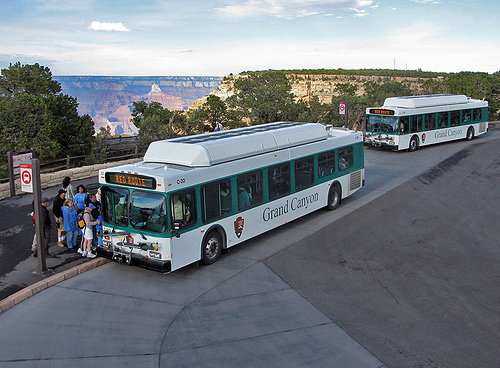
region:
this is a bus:
[94, 120, 368, 273]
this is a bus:
[364, 85, 496, 149]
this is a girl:
[78, 200, 99, 259]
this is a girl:
[59, 193, 86, 248]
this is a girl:
[37, 191, 58, 263]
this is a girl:
[49, 183, 71, 248]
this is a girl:
[54, 165, 80, 240]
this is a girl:
[65, 182, 100, 234]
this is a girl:
[84, 189, 103, 251]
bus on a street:
[95, 138, 400, 269]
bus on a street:
[360, 83, 492, 159]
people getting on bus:
[56, 175, 97, 260]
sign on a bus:
[102, 170, 162, 192]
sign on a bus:
[368, 102, 394, 120]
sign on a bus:
[251, 188, 332, 228]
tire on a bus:
[201, 225, 236, 265]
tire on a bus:
[322, 180, 359, 208]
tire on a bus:
[405, 135, 430, 151]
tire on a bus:
[458, 126, 478, 143]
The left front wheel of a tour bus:
[194, 222, 230, 266]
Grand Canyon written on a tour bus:
[253, 187, 326, 227]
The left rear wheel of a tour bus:
[317, 174, 346, 214]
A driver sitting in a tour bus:
[156, 189, 195, 231]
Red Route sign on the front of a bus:
[102, 170, 153, 193]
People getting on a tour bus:
[52, 174, 104, 262]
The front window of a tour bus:
[92, 180, 170, 240]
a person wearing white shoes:
[77, 245, 99, 262]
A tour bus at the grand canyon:
[89, 113, 371, 278]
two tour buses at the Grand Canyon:
[94, 87, 492, 283]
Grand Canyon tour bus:
[82, 117, 372, 282]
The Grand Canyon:
[46, 73, 253, 138]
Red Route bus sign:
[103, 170, 160, 190]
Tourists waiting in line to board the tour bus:
[30, 168, 133, 275]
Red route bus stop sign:
[16, 155, 51, 280]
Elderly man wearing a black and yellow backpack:
[75, 198, 104, 259]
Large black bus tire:
[198, 228, 230, 264]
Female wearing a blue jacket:
[61, 195, 81, 252]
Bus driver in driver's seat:
[146, 170, 223, 275]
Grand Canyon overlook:
[37, 71, 236, 170]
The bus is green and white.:
[362, 88, 494, 154]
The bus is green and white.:
[97, 115, 370, 279]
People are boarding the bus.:
[18, 118, 373, 285]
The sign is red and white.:
[15, 155, 38, 197]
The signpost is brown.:
[25, 156, 50, 276]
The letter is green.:
[261, 204, 271, 222]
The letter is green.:
[289, 195, 298, 214]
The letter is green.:
[283, 196, 291, 214]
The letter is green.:
[276, 198, 285, 220]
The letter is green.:
[272, 203, 280, 222]